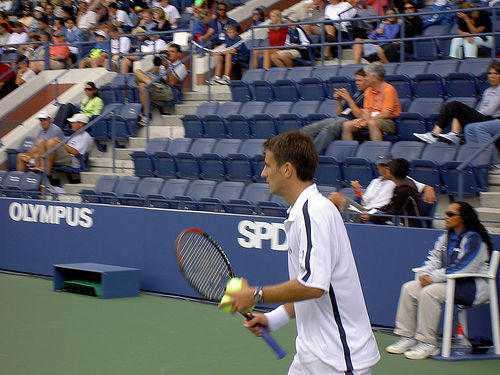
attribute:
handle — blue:
[255, 325, 286, 358]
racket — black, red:
[171, 226, 289, 365]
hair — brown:
[267, 133, 318, 181]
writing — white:
[5, 197, 95, 228]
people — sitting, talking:
[348, 156, 437, 230]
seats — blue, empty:
[81, 44, 499, 210]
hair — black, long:
[463, 203, 498, 260]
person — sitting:
[385, 204, 500, 374]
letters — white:
[236, 221, 292, 253]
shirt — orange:
[364, 84, 406, 117]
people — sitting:
[326, 63, 407, 146]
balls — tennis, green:
[217, 279, 246, 310]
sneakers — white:
[382, 333, 449, 361]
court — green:
[0, 274, 499, 370]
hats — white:
[35, 112, 94, 127]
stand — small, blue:
[53, 257, 142, 299]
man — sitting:
[129, 43, 189, 120]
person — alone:
[65, 71, 109, 119]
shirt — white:
[353, 169, 434, 222]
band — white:
[264, 303, 296, 332]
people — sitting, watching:
[0, 2, 499, 134]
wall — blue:
[0, 192, 494, 352]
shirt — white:
[288, 187, 381, 374]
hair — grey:
[364, 60, 390, 76]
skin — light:
[260, 280, 326, 302]